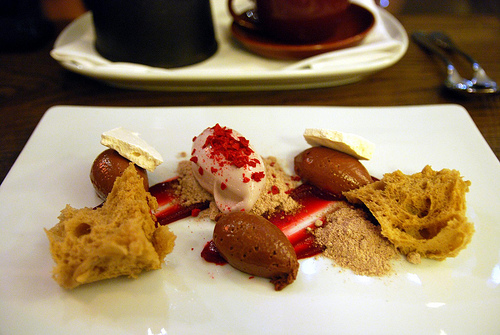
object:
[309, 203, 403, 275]
powder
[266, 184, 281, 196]
crumbles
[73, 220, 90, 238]
hole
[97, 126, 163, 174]
butter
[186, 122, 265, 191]
sprinkle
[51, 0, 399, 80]
napkin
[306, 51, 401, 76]
napkin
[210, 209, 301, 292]
piece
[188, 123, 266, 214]
piece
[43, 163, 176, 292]
piece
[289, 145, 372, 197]
piece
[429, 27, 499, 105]
silverware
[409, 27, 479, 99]
silverware table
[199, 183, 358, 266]
sauce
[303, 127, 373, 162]
food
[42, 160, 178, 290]
food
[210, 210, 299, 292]
food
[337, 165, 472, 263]
food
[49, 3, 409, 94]
plates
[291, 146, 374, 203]
food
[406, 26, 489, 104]
silverware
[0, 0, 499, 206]
table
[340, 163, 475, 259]
piece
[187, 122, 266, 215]
cream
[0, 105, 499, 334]
plate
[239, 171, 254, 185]
flakes